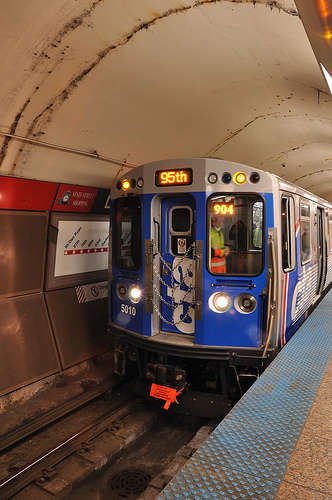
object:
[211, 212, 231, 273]
person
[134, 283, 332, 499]
floor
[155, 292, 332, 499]
tile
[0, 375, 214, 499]
rail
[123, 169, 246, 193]
rear lights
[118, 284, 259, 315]
rear lights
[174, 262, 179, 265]
link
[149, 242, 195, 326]
chains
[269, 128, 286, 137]
ground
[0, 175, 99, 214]
sign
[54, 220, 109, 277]
posters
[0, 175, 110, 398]
wall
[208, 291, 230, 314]
headlight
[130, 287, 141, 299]
headlight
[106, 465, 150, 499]
lid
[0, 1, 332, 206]
roof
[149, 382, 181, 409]
orange sign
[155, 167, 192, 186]
led display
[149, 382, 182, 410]
red tag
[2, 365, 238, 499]
track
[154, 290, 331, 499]
blue edge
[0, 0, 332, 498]
photo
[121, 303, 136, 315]
number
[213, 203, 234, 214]
sign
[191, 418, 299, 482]
circles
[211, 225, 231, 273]
safety clothing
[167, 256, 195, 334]
cta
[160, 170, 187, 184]
95th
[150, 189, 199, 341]
door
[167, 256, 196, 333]
letters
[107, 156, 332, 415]
train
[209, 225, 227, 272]
vest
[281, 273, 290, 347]
stripe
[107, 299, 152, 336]
left corner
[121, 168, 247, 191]
light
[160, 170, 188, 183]
number